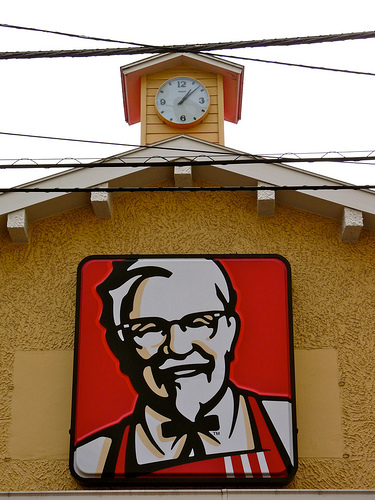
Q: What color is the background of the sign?
A: Red.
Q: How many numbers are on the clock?
A: Four.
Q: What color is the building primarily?
A: Yellow.